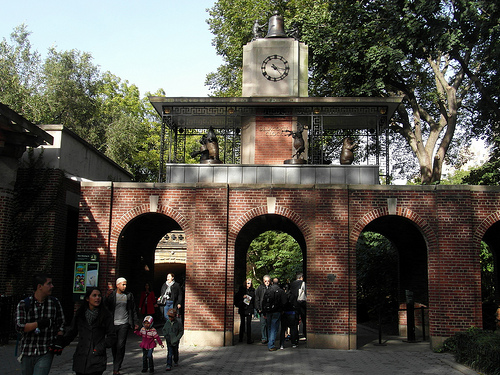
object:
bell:
[263, 4, 289, 38]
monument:
[233, 8, 329, 190]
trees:
[231, 2, 499, 180]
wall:
[46, 130, 497, 354]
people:
[233, 266, 305, 346]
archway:
[229, 199, 309, 354]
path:
[177, 341, 452, 374]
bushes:
[438, 320, 499, 373]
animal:
[188, 126, 223, 164]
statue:
[340, 136, 357, 166]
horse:
[282, 121, 312, 158]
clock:
[259, 54, 288, 82]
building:
[148, 0, 386, 189]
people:
[116, 257, 180, 333]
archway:
[107, 203, 198, 346]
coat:
[133, 325, 159, 349]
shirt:
[14, 295, 69, 356]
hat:
[115, 277, 128, 284]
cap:
[167, 309, 176, 318]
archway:
[355, 211, 427, 350]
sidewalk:
[345, 317, 452, 370]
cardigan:
[164, 281, 174, 299]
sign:
[71, 251, 100, 302]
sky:
[9, 6, 224, 92]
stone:
[246, 37, 314, 101]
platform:
[162, 153, 383, 188]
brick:
[206, 194, 225, 277]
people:
[10, 274, 191, 375]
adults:
[98, 275, 140, 374]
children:
[133, 315, 165, 372]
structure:
[53, 171, 264, 346]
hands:
[269, 66, 288, 74]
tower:
[246, 3, 295, 185]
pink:
[145, 341, 151, 346]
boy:
[161, 309, 184, 371]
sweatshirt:
[163, 320, 183, 345]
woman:
[52, 286, 115, 375]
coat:
[72, 305, 111, 359]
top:
[243, 28, 311, 56]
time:
[270, 66, 293, 81]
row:
[77, 258, 471, 307]